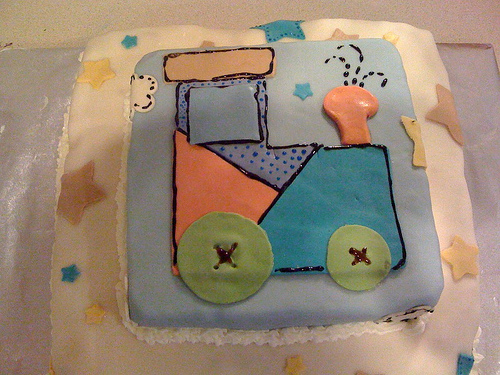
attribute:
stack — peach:
[343, 81, 433, 141]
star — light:
[444, 233, 484, 284]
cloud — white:
[129, 72, 158, 119]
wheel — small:
[324, 222, 394, 293]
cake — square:
[45, 15, 486, 374]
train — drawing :
[159, 46, 409, 308]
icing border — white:
[116, 314, 427, 349]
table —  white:
[2, 1, 499, 373]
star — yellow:
[76, 54, 120, 95]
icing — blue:
[67, 41, 400, 352]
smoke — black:
[329, 41, 391, 91]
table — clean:
[12, 32, 497, 369]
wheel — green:
[156, 204, 308, 319]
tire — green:
[161, 208, 292, 301]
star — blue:
[290, 73, 323, 103]